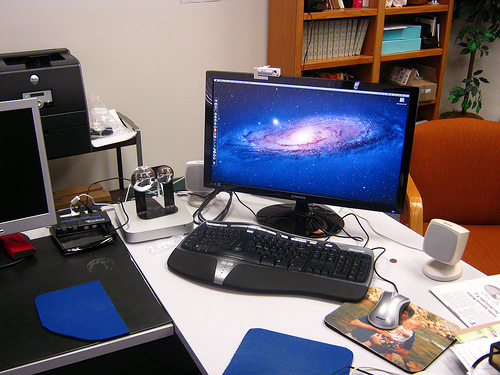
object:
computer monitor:
[208, 79, 410, 206]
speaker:
[422, 219, 469, 283]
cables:
[193, 188, 296, 233]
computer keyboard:
[166, 219, 374, 302]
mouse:
[365, 290, 411, 330]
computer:
[202, 69, 419, 239]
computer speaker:
[423, 218, 471, 282]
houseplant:
[446, 0, 499, 116]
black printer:
[0, 47, 92, 159]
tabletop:
[0, 190, 499, 374]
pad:
[34, 280, 130, 341]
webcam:
[273, 70, 277, 74]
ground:
[0, 190, 499, 375]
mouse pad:
[324, 287, 462, 375]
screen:
[204, 71, 418, 213]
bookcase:
[266, 2, 452, 120]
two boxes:
[381, 25, 422, 54]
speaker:
[185, 160, 216, 207]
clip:
[253, 65, 281, 81]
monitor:
[0, 106, 49, 223]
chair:
[406, 117, 500, 275]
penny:
[389, 258, 397, 263]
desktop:
[203, 64, 420, 213]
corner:
[438, 74, 490, 122]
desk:
[0, 187, 499, 374]